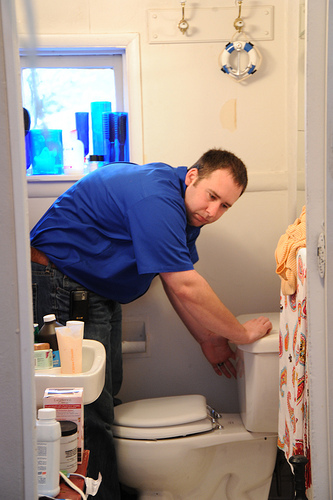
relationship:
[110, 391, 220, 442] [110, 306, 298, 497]
lid of toilet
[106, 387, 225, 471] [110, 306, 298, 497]
seat of toilet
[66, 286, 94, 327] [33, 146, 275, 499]
phone on side of man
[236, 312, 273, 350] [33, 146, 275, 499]
hand of man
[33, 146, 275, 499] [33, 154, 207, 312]
man wearing shirt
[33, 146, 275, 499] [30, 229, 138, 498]
man wearing jeans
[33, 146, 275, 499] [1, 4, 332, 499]
man inside bathroom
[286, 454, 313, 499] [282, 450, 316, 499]
handle of plunger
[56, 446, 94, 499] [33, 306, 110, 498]
sink with products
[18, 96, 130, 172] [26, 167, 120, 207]
items on window sill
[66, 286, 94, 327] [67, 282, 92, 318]
phone in case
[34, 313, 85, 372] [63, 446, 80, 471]
bottle with label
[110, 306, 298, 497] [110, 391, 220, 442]
toilet has lid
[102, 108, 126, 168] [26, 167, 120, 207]
hairbrushes on window sill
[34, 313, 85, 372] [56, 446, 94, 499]
bottle on sink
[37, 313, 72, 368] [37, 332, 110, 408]
bottle on pedestal sink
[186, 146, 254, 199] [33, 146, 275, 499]
hair of man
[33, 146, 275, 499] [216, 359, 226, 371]
man wearing wedding ring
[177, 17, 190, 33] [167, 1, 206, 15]
hook on rack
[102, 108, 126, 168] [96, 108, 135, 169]
hairbrushes on jar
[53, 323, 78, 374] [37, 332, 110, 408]
container on pedestal sink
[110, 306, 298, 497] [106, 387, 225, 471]
toilet has seat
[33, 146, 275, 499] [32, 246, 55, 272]
man wearing belt